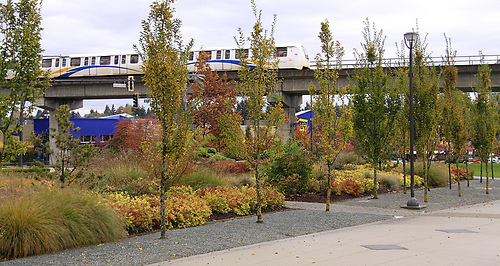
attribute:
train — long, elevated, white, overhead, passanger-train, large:
[5, 43, 313, 79]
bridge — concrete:
[1, 55, 500, 98]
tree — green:
[134, 0, 195, 238]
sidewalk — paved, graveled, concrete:
[1, 177, 499, 266]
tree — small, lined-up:
[217, 2, 285, 224]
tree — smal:
[305, 18, 355, 214]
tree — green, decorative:
[353, 19, 403, 198]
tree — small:
[403, 25, 442, 201]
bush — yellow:
[99, 190, 157, 235]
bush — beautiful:
[145, 187, 213, 228]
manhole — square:
[361, 241, 409, 254]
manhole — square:
[435, 226, 477, 235]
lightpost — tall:
[401, 26, 425, 209]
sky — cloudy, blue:
[1, 2, 499, 69]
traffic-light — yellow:
[127, 75, 136, 91]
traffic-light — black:
[133, 90, 140, 110]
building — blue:
[33, 118, 141, 151]